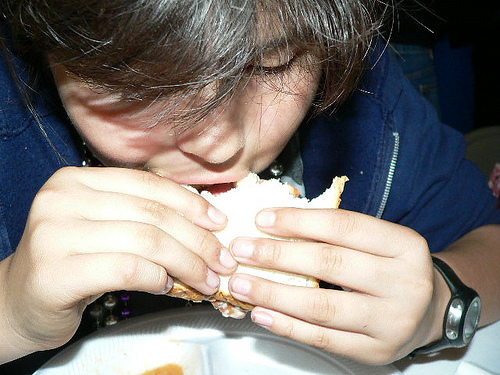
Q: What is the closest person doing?
A: Eating.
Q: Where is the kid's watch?
A: His left wrist.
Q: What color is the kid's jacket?
A: Blue.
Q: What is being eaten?
A: Sandwich.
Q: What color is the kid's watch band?
A: Black.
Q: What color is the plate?
A: White.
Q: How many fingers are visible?
A: 8.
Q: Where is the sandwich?
A: Kid's hands.